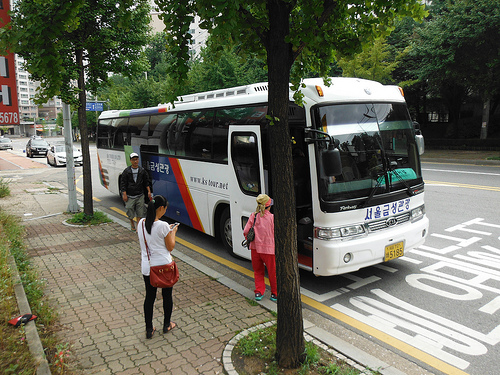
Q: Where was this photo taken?
A: Asia.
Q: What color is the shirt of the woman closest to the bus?
A: Pink.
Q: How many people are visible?
A: Three.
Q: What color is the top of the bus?
A: White.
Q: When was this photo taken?
A: Day time.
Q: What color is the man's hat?
A: White.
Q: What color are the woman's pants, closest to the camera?
A: Black.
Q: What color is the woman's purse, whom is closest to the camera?
A: Red.